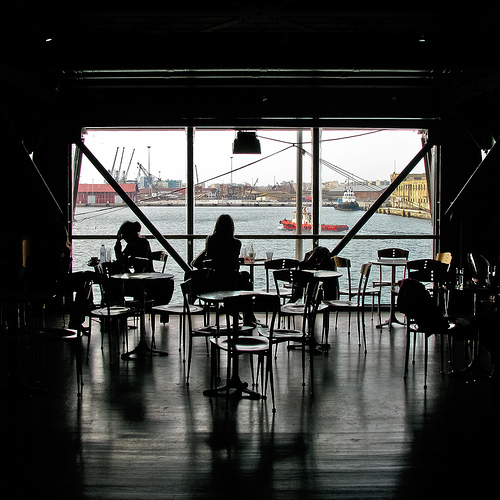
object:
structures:
[117, 156, 281, 198]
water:
[71, 202, 431, 303]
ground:
[371, 203, 428, 217]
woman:
[110, 222, 154, 273]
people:
[47, 213, 258, 334]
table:
[108, 272, 174, 360]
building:
[75, 184, 140, 206]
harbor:
[39, 198, 439, 304]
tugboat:
[266, 217, 374, 247]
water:
[201, 191, 333, 251]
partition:
[82, 196, 369, 210]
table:
[193, 285, 280, 405]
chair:
[210, 293, 281, 416]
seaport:
[83, 177, 470, 344]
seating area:
[0, 220, 500, 415]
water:
[199, 203, 260, 227]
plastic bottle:
[100, 245, 106, 264]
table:
[85, 259, 148, 272]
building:
[389, 173, 430, 213]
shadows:
[209, 395, 307, 493]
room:
[0, 0, 499, 499]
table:
[369, 257, 410, 327]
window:
[69, 125, 434, 305]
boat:
[279, 207, 349, 231]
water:
[76, 205, 436, 240]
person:
[281, 246, 340, 305]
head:
[215, 214, 235, 237]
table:
[274, 270, 342, 347]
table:
[0, 264, 70, 338]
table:
[198, 288, 267, 400]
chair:
[19, 271, 88, 400]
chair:
[180, 276, 218, 390]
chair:
[258, 268, 314, 410]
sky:
[75, 125, 433, 191]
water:
[74, 205, 427, 306]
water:
[164, 196, 176, 246]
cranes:
[103, 146, 137, 184]